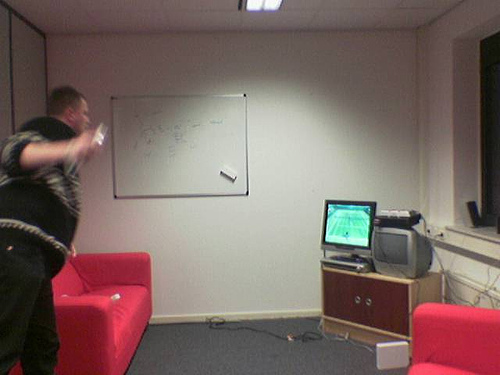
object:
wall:
[50, 29, 427, 314]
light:
[247, 2, 280, 10]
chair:
[409, 300, 499, 373]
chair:
[51, 252, 151, 373]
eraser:
[217, 164, 237, 182]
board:
[113, 91, 248, 195]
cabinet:
[312, 259, 414, 354]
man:
[3, 80, 105, 374]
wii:
[374, 339, 409, 374]